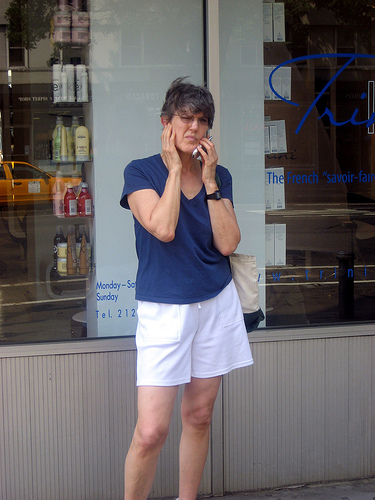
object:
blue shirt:
[120, 153, 235, 305]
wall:
[260, 329, 374, 500]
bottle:
[64, 183, 78, 217]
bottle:
[75, 116, 90, 161]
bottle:
[53, 181, 65, 219]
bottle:
[57, 242, 67, 276]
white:
[142, 303, 238, 382]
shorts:
[135, 278, 253, 387]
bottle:
[71, 116, 80, 156]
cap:
[72, 115, 78, 124]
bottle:
[78, 182, 93, 217]